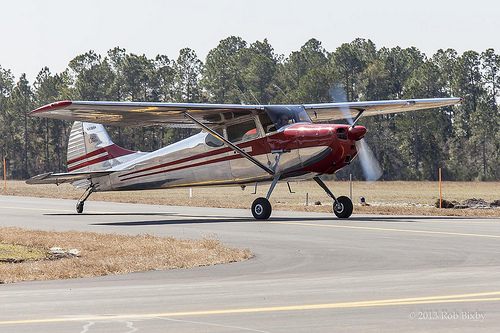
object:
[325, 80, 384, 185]
propeller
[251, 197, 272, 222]
tire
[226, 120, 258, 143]
window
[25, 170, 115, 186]
tail wing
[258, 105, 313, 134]
window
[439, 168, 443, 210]
post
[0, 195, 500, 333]
runway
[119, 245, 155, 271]
grass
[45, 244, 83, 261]
stone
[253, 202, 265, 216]
trim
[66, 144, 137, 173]
stripe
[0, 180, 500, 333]
ground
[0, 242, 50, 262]
grass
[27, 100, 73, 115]
red edge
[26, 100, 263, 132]
wing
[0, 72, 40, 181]
trees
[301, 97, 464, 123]
wing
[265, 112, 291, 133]
pilot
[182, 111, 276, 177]
beam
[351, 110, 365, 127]
beam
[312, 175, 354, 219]
landing gear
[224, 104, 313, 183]
cockpit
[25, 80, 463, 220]
airport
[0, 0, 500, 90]
sky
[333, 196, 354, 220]
front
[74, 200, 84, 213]
back